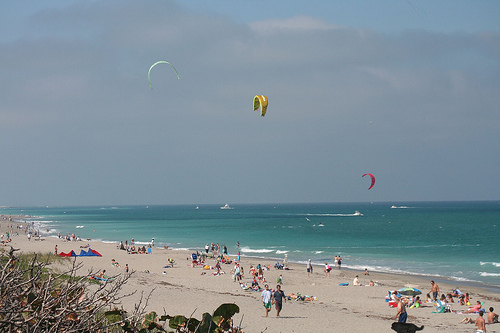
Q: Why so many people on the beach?
A: Warm weather.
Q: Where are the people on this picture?
A: In the beach.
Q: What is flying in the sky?
A: Kites.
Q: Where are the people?
A: Beach.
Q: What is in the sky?
A: A parasail.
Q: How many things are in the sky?
A: Three.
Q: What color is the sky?
A: Blue.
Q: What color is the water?
A: Blue.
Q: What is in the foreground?
A: A scrubby bush.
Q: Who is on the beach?
A: Some people.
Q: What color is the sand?
A: Brown.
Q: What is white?
A: Waves.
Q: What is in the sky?
A: Clouds.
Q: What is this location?
A: A beach.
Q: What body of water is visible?
A: An ocean.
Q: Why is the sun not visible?
A: It's overcast.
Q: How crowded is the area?
A: Minimally.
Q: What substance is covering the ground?
A: Sand.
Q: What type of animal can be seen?
A: A dog.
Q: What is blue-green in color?
A: The ocean water.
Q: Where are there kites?
A: In the sky.